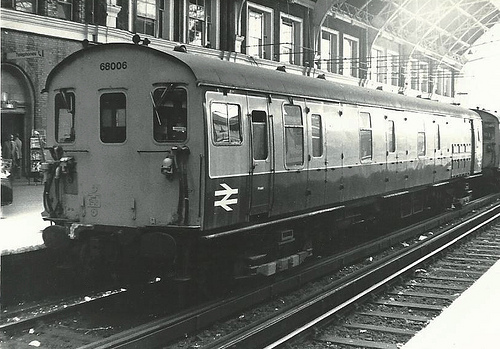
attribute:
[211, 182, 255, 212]
symbol — white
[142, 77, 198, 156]
window — small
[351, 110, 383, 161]
window — small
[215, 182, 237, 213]
symbol — white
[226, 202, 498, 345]
tracks — empty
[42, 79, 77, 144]
window — small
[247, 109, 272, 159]
window — small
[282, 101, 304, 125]
window — small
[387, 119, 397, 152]
window — small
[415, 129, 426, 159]
window — small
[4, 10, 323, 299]
station — train